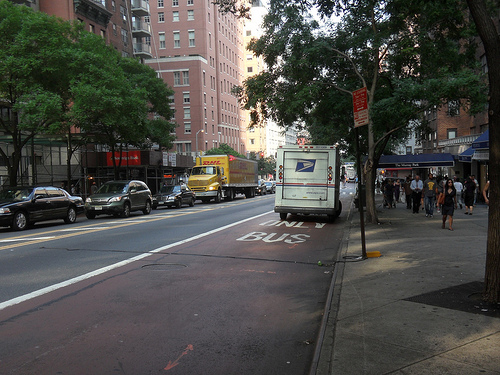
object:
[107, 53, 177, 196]
tree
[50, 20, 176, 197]
tree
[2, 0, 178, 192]
tree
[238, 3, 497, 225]
tree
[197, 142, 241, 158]
trees